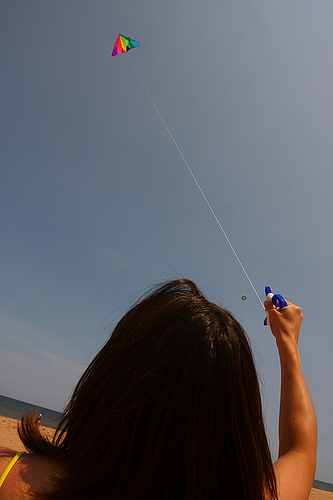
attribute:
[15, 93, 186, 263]
sky — blue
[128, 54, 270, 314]
white string — long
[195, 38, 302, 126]
sky — blue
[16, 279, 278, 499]
hair — black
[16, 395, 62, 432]
water — calm, blue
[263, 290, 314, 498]
arm — in the air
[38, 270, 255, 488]
hair — Brown, long, smooth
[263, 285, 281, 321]
holder — blue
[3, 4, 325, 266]
sky — blue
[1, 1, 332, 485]
sky — blue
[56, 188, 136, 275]
sky — blue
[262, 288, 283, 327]
handle — blue, plastic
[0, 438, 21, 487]
strap — yellow